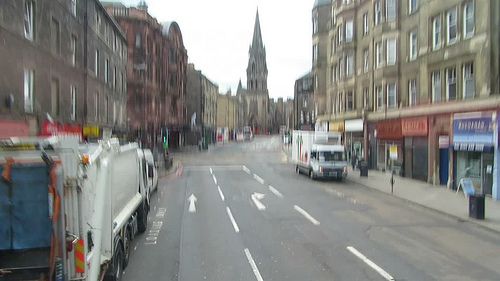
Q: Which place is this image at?
A: It is at the road.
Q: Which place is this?
A: It is a road.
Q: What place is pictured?
A: It is a road.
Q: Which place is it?
A: It is a road.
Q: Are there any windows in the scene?
A: Yes, there is a window.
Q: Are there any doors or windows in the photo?
A: Yes, there is a window.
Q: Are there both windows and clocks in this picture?
A: No, there is a window but no clocks.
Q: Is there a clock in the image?
A: No, there are no clocks.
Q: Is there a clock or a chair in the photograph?
A: No, there are no clocks or chairs.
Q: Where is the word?
A: The word is on the road.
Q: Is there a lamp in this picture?
A: No, there are no lamps.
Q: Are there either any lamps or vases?
A: No, there are no lamps or vases.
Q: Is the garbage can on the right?
A: Yes, the garbage can is on the right of the image.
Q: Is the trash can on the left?
A: No, the trash can is on the right of the image.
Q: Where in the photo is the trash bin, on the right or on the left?
A: The trash bin is on the right of the image.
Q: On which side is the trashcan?
A: The trashcan is on the right of the image.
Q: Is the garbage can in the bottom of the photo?
A: Yes, the garbage can is in the bottom of the image.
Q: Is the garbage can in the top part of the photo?
A: No, the garbage can is in the bottom of the image.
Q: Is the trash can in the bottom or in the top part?
A: The trash can is in the bottom of the image.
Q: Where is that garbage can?
A: The garbage can is on the sidewalk.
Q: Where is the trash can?
A: The garbage can is on the sidewalk.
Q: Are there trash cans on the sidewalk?
A: Yes, there is a trash can on the sidewalk.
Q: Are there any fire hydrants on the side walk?
A: No, there is a trash can on the side walk.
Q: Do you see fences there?
A: No, there are no fences.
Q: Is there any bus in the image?
A: No, there are no buses.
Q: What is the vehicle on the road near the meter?
A: The vehicle is a van.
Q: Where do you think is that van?
A: The van is on the road.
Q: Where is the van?
A: The van is on the road.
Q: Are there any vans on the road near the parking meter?
A: Yes, there is a van on the road.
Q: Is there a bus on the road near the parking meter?
A: No, there is a van on the road.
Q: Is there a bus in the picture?
A: No, there are no buses.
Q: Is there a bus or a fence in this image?
A: No, there are no buses or fences.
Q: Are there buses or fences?
A: No, there are no buses or fences.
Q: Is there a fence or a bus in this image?
A: No, there are no buses or fences.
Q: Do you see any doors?
A: Yes, there is a door.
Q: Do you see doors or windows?
A: Yes, there is a door.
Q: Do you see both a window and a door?
A: Yes, there are both a door and a window.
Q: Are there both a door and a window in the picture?
A: Yes, there are both a door and a window.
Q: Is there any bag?
A: No, there are no bags.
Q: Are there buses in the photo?
A: No, there are no buses.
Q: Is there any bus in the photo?
A: No, there are no buses.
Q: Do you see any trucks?
A: Yes, there is a truck.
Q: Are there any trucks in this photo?
A: Yes, there is a truck.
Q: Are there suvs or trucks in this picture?
A: Yes, there is a truck.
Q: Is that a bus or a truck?
A: That is a truck.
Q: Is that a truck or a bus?
A: That is a truck.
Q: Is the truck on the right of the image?
A: No, the truck is on the left of the image.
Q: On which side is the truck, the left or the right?
A: The truck is on the left of the image.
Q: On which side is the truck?
A: The truck is on the left of the image.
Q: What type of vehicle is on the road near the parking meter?
A: The vehicle is a truck.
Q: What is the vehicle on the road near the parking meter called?
A: The vehicle is a truck.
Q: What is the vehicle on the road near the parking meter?
A: The vehicle is a truck.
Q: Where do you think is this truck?
A: The truck is on the road.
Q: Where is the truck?
A: The truck is on the road.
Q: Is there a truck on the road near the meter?
A: Yes, there is a truck on the road.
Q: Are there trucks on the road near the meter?
A: Yes, there is a truck on the road.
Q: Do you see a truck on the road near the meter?
A: Yes, there is a truck on the road.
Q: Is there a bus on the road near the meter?
A: No, there is a truck on the road.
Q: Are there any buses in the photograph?
A: No, there are no buses.